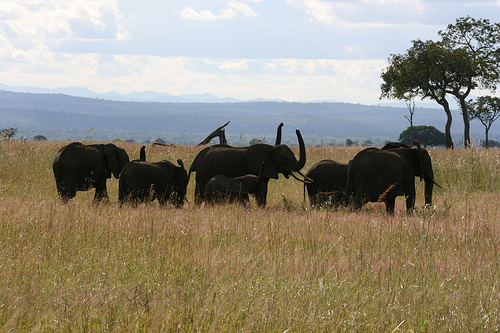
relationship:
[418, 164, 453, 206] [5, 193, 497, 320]
hanging trunk on ground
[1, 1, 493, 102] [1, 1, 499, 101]
clouds in sky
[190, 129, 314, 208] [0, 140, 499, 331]
elephant on plain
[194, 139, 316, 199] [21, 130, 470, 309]
elephant on plain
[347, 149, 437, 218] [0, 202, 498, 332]
elephant on plain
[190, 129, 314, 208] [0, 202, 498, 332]
elephant on plain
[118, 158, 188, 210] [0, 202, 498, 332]
elephant on plain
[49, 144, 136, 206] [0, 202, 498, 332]
elephant on plain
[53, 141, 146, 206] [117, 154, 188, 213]
elephant next to elephant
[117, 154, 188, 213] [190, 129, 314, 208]
elephant next to elephant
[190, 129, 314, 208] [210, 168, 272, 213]
elephant next to elephant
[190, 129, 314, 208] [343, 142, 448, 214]
elephant next to elephant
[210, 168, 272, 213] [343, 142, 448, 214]
elephant next to elephant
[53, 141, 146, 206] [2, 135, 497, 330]
elephant in field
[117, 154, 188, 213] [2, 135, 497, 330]
elephant in field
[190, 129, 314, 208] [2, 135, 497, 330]
elephant in field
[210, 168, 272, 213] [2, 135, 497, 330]
elephant in field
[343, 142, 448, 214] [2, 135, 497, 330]
elephant in field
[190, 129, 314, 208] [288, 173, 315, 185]
elephant has tusks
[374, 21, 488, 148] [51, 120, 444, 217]
trees behind elephants